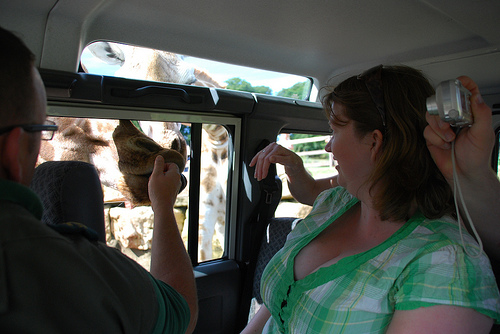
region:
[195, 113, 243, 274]
window on a bus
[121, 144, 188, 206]
mouth of a giraffe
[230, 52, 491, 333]
large lady with brown hair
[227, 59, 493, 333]
large lady wearing a green shirt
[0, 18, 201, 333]
person with fingers in a giraffes mouth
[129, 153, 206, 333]
arm of a person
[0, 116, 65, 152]
pair of black eye glasses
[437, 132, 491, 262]
white cord on a camera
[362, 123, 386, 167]
ear of a lady in green shirt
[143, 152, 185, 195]
his hand is in the giraffes mouth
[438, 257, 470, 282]
the shirt is plaid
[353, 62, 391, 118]
the sunglasses are on her head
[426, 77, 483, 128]
the person is holding the camera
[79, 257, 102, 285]
the shirt is gray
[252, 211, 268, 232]
the belt is black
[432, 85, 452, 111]
the camera is silver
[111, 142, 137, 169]
the giraffe is brown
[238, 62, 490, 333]
woman in a green and white shirt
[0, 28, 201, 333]
man in a dark green shirt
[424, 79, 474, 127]
gray camera in the person's hand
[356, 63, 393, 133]
black sunglasses on the woman's head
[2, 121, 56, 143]
black eyeglasses on the man's face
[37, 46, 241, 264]
two giraffes outside the window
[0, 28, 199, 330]
man feeding a giraffe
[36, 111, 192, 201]
giraffe eatting from the man's hand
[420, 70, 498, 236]
person taking a picture of the giraffe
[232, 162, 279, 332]
seat belt inside the car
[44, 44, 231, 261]
two giraffes outside the window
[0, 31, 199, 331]
man feeding the giraffe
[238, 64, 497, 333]
woman sitting in the van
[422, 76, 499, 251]
person taking pictures of the animals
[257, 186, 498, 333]
green and white shirt on the woman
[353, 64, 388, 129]
black shades on the woman's head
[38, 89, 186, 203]
giraffe being fed by the man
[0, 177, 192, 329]
green shirt on the man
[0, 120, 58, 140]
black eyeglasses on the man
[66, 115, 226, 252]
a window on the bus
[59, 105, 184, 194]
a giraffe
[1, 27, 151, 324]
a man with glasses on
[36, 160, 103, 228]
the seat in the bus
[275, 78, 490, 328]
a lady in a green shirt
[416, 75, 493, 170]
a person taking a picture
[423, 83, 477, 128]
a silver camera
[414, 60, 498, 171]
a hand holding a camera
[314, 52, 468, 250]
a lady with sunglasses on her head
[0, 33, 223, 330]
a man petting a giraffe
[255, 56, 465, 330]
Woman looking to her right at the animals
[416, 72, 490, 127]
Person holding the camera and taking a picture of the animal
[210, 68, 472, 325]
Woman wearing a tight shirt and smiling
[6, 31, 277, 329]
Man putting his hand in the animal's mouth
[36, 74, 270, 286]
Window rolled down do the animal can suck on the hands of the passengers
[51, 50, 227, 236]
Giraffe is sticking its mouth into the car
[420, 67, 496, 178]
a hand holding the camera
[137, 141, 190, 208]
A hand touching a giraffe mouth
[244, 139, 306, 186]
A hand attempting to pet the giraffe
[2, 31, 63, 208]
A Person wearing a pair of glasses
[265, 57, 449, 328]
a Woman looking at the giraffe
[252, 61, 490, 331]
a Lady wearing a green and white top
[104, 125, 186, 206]
A giraffe Eating from the person's hand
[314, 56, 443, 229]
A Woman with short brown hair